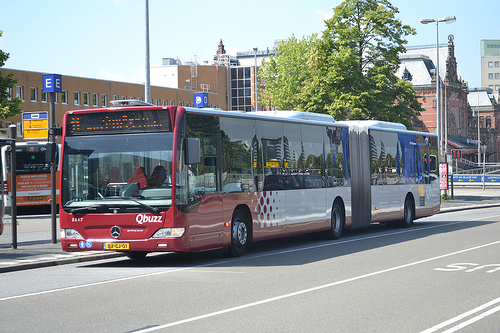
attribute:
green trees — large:
[251, 6, 428, 121]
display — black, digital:
[68, 110, 173, 135]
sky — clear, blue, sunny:
[6, 5, 481, 72]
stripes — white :
[262, 264, 430, 288]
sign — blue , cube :
[25, 51, 89, 108]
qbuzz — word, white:
[134, 212, 166, 229]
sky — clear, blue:
[45, 16, 112, 51]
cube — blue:
[43, 72, 63, 92]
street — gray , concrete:
[15, 229, 499, 329]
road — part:
[9, 197, 494, 331]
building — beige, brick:
[3, 55, 233, 121]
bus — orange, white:
[4, 132, 79, 220]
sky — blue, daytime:
[6, 7, 491, 87]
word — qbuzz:
[122, 209, 166, 230]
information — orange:
[91, 119, 145, 124]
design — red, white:
[212, 192, 316, 234]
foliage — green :
[268, 68, 306, 102]